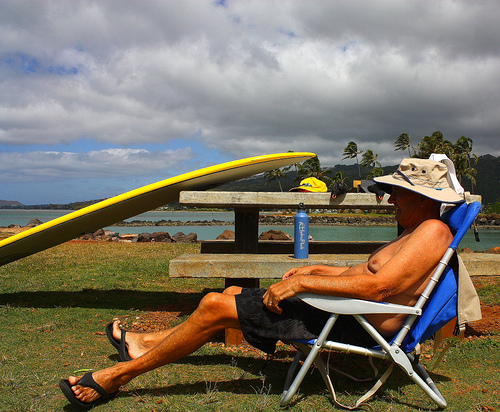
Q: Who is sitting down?
A: A man.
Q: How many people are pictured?
A: One.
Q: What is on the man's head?
A: A hat.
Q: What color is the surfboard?
A: Yellow.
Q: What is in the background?
A: Water and palm trees.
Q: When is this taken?
A: Daytime.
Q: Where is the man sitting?
A: In a lawnchair.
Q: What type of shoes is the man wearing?
A: Sandals.